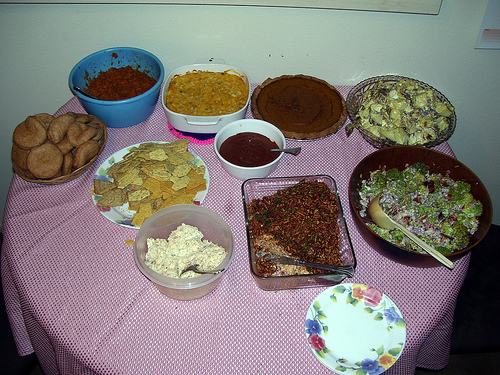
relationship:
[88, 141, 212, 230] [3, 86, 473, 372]
dish on table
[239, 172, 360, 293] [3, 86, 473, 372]
dish on table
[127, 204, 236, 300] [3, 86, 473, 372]
dish on table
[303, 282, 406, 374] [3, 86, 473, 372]
plate on table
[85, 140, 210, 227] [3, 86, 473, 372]
crackers on table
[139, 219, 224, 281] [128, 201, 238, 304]
chicken salad in bowl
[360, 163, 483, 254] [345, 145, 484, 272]
food in bowl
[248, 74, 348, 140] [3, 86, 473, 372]
pie on table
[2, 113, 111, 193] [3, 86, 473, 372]
basket on table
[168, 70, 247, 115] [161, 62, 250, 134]
corn in dish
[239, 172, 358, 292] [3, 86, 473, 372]
food on table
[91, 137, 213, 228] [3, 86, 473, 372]
food on table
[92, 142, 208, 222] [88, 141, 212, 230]
chips on dish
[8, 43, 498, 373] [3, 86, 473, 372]
food on top of table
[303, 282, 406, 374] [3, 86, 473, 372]
plate on top of table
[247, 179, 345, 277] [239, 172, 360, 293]
food in dish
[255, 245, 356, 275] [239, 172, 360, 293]
spoon in dish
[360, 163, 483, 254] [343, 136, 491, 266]
food in bowl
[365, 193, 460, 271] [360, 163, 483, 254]
server in food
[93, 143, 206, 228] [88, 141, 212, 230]
food on top of dish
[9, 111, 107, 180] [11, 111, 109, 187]
bread pieces in basket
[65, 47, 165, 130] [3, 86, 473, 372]
bowl on table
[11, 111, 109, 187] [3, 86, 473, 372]
basket on table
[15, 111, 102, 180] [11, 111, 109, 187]
bread in basket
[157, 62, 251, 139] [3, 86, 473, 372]
dish on table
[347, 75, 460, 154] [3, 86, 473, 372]
bowl on table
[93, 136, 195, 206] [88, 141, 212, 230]
crackers sitting on dish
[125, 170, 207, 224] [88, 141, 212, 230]
cheese sitting on dish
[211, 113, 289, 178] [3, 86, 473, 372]
bowl sitting on table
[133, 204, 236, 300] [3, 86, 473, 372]
dish sitting on table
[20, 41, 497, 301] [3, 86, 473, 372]
food sitting on table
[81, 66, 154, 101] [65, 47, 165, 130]
salsa in bowl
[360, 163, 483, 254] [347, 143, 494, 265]
food in bowl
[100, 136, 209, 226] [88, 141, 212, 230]
crackers on dish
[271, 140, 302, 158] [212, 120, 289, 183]
spoon in bowl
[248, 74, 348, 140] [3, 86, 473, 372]
pie sitting on table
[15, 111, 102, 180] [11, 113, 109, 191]
bread in basket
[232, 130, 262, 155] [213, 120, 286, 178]
salsa inside of bowl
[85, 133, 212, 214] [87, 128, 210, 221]
chips are on top of plate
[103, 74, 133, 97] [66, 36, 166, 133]
salsa inside of bowl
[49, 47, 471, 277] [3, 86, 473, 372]
food on top of table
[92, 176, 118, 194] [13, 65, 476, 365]
crackers on top of table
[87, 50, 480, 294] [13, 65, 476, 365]
food on top of table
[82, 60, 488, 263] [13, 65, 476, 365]
food on top of table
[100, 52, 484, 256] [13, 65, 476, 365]
food on top of table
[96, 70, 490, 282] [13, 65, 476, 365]
food on top of table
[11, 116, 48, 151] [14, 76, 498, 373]
bread on top of table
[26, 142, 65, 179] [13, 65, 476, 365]
bread on top of table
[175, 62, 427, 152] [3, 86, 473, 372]
food on top of table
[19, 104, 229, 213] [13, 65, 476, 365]
food on top of table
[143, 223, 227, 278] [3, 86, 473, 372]
chicken salad on top of table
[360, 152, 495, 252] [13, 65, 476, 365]
food on top of table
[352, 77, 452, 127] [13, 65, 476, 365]
food on top of table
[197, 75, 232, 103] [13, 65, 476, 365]
food on top of table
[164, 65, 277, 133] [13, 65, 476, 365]
food on top of table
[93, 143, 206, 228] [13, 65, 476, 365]
food on top of table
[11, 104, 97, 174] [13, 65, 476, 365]
bread on top of table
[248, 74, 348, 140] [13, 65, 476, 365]
pie on top of table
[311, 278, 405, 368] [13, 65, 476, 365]
plate on top of table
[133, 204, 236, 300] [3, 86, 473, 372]
dish on table